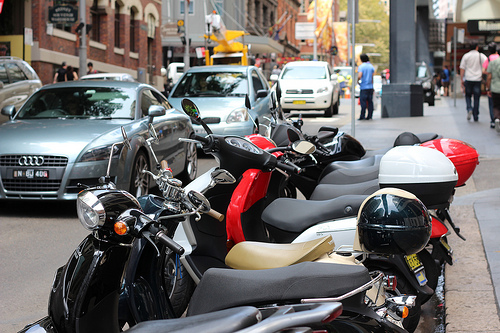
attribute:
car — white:
[271, 59, 345, 120]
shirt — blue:
[357, 62, 376, 93]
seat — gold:
[223, 236, 336, 269]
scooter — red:
[238, 135, 460, 262]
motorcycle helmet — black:
[350, 188, 437, 261]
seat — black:
[185, 263, 370, 310]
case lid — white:
[374, 144, 461, 182]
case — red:
[424, 136, 482, 190]